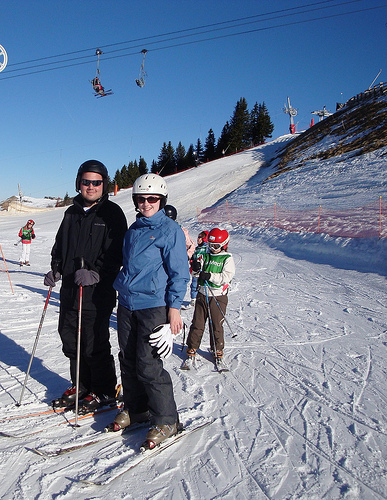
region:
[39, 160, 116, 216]
the guy in black helmet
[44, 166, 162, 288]
the guy in black helmet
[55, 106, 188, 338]
the guy in black helmet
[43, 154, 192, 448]
Two adults on a ski hill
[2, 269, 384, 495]
ski tracks fill the ground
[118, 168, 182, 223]
woman wearing white helmet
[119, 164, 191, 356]
woman holding white gloves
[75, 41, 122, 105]
people on a ski lift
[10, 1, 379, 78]
wires of a ski lift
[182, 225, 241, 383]
child wearing ski gear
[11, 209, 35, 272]
person in white ski pants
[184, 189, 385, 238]
orange net fence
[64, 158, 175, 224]
two people wearing sunglasses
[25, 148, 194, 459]
man and woman standing on skis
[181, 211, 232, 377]
child standing on skis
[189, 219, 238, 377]
child wearing red helmet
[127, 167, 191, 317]
woman wearing white helmet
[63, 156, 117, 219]
man wearing black helmet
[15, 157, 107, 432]
man holding two ski poles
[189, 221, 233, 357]
child wearing brown pants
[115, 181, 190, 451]
woman holding two white gloves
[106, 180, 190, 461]
woman wearing light brown ski boots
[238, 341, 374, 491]
ski marks in the white snow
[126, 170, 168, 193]
The white helmet on the lady's head.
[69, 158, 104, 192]
The black helmet on the man's head.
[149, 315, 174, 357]
The white gloves the lady is holding.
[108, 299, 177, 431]
The black pants the lady is wearing.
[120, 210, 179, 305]
The blue jacket the lady is wearing.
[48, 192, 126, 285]
The black jacket the man is wearing.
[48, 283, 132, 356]
The black pants the man is wearing.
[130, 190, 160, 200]
The sunglasses the lady is wearing.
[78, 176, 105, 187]
The sunglasses the man is wearing.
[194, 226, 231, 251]
The red helmets the kids are wearing.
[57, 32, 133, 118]
people riding ski lift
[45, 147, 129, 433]
man standing in snow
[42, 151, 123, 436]
man holding ski poles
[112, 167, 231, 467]
lady wearing skis in snow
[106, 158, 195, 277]
lady wearing white helmet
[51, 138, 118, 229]
guy wearing black helmet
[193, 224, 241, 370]
kid wearing skis in snow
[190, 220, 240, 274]
kid wearing white goggles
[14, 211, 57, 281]
person wearing white pants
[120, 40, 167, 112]
empty chair on ski lift